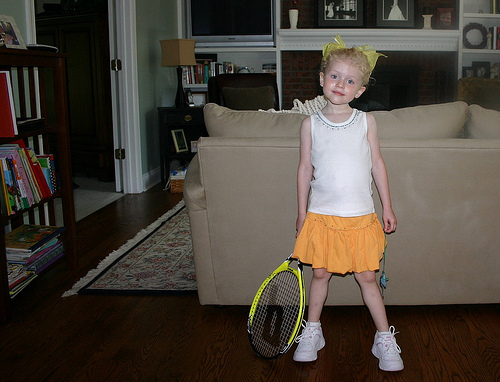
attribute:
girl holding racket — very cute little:
[247, 43, 412, 374]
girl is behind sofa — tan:
[187, 38, 498, 371]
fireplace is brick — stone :
[281, 43, 463, 108]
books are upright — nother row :
[3, 140, 60, 216]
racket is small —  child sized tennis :
[245, 251, 307, 361]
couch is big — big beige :
[187, 107, 500, 308]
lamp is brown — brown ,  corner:
[162, 36, 192, 108]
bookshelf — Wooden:
[4, 6, 86, 274]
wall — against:
[136, 8, 169, 128]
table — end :
[148, 93, 200, 191]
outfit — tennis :
[291, 110, 393, 275]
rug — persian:
[74, 186, 200, 302]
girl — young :
[251, 30, 414, 380]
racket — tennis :
[243, 250, 306, 362]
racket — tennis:
[241, 232, 318, 373]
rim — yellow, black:
[291, 281, 310, 347]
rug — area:
[63, 199, 201, 299]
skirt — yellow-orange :
[293, 206, 389, 269]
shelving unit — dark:
[3, 46, 78, 318]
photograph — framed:
[0, 19, 20, 47]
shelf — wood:
[0, 48, 77, 329]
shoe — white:
[370, 325, 407, 374]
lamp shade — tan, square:
[156, 34, 198, 69]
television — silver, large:
[185, 1, 273, 45]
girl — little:
[293, 36, 407, 375]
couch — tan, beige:
[183, 101, 498, 305]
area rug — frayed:
[61, 196, 198, 299]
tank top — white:
[303, 105, 375, 220]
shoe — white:
[292, 315, 326, 364]